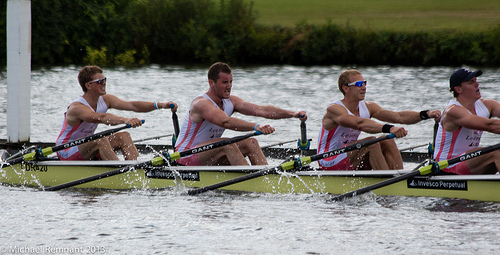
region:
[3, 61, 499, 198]
Men rowing a boat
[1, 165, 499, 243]
Choppy water from rowing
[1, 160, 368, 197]
Water splashing up from oars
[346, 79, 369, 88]
Blue and white sunglasses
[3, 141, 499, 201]
Yellow-green row boat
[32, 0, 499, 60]
Grass and bushes on the bank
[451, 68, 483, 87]
Black baseball cap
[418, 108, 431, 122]
Black elastic wrist cuff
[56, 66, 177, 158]
Rower in pink and white uniform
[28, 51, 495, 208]
men in boat on water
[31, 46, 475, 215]
men rowing boat in water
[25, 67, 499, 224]
men rowing yellow boat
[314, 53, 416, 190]
man rowing with blue sunglasses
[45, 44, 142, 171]
man rowing with sunglasses on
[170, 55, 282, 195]
only man in boat with nude head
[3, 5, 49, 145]
white post in water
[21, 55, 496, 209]
men in matching uniforms rowing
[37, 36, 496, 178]
men on a row team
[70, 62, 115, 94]
Man wearing white sunglasses.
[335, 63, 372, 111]
man wearing white sunglasses with blue lenses.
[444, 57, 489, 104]
Man wearing a black hat on his head.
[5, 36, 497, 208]
Four men rowing on a row boat.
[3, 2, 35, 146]
Large white pillar in the water.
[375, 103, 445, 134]
Two black sweatbands on his wrists.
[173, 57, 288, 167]
Man wearing a white and orange uniform.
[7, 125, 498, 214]
Green row boats with black oars.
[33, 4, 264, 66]
Green bushes growing alongside the bank.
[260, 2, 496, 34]
Grass growing the background.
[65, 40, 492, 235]
people sitting in boat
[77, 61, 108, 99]
man has brown hair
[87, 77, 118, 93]
man is wearing sunglasses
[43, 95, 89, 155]
white and red shirt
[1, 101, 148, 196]
black and yellow oar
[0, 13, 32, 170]
white pole behind men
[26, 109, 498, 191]
yellow and black boat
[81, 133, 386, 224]
small wake near boat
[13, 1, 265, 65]
green trees on shore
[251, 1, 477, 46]
green and brown grass behind trees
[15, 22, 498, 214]
Rowing team sitting in the canoe.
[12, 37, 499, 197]
Four men rowing together.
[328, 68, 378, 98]
Man wearing sunglasses with blue lenses.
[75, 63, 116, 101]
Man wearing white sunglasses.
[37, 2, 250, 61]
Large bushes growing alongside the bank.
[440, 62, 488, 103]
Man wearing a black hat.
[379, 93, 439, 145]
Black sweatbands on the man's wrists.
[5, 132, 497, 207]
Large green row boat.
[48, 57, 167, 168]
Man wearing a white and orange uniform.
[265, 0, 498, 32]
Grass growing in the distance.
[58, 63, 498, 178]
four men on a boat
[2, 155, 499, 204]
a yellow boat in the water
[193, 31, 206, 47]
green leaves on the tree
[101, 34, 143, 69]
green leaves on the tree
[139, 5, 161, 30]
green leaves on the tree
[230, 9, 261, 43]
green leaves on the tree